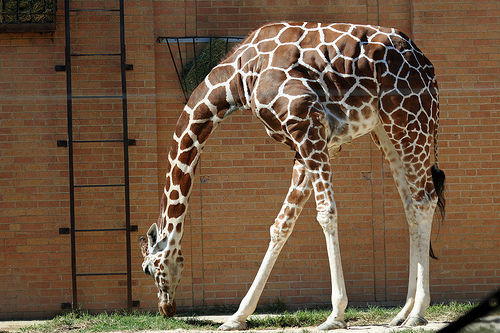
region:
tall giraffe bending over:
[126, 78, 422, 325]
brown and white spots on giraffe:
[276, 38, 338, 83]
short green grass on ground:
[66, 280, 356, 332]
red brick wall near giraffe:
[36, 26, 495, 291]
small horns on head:
[134, 228, 154, 260]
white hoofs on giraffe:
[195, 271, 465, 324]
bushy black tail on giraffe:
[418, 127, 454, 210]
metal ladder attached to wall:
[35, 10, 174, 326]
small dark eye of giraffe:
[136, 261, 161, 281]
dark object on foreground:
[404, 298, 484, 332]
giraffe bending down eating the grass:
[141, 22, 446, 327]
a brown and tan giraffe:
[143, 22, 443, 324]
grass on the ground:
[10, 304, 498, 330]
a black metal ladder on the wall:
[59, 5, 144, 312]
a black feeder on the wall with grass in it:
[153, 32, 244, 117]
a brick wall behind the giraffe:
[9, 8, 499, 303]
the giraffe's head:
[140, 225, 185, 318]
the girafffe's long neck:
[155, 53, 247, 235]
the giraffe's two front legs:
[222, 155, 349, 330]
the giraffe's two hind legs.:
[379, 70, 439, 326]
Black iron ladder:
[53, 3, 141, 317]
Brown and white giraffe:
[133, 18, 452, 329]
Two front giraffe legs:
[222, 148, 355, 330]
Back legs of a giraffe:
[373, 128, 441, 328]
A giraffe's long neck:
[158, 58, 242, 240]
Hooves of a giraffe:
[387, 313, 432, 330]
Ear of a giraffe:
[144, 219, 163, 255]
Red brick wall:
[6, 40, 59, 312]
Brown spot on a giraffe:
[268, 42, 302, 70]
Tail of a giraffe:
[430, 85, 447, 223]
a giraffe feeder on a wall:
[148, 24, 248, 106]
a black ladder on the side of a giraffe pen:
[56, 0, 137, 313]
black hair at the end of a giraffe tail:
[424, 162, 449, 266]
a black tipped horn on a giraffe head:
[136, 233, 149, 256]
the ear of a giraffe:
[146, 221, 164, 247]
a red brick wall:
[1, 2, 497, 320]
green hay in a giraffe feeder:
[182, 36, 234, 94]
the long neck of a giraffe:
[159, 56, 249, 238]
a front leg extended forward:
[221, 159, 304, 331]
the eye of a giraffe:
[143, 261, 153, 274]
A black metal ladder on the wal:
[60, 0, 135, 312]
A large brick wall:
[0, 0, 495, 320]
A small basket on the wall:
[155, 31, 247, 107]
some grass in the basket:
[181, 32, 228, 89]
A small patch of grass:
[15, 305, 215, 330]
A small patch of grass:
[250, 300, 475, 325]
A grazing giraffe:
[136, 18, 451, 325]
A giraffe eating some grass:
[136, 18, 450, 331]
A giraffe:
[137, 13, 451, 330]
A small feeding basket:
[161, 26, 248, 105]